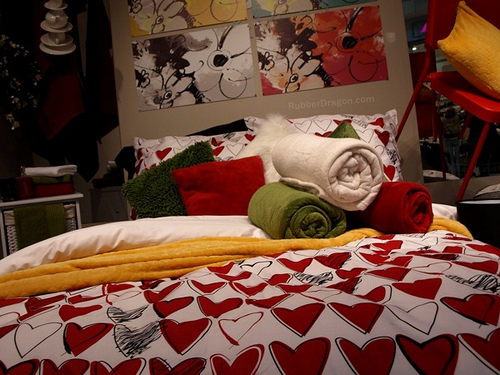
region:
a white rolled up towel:
[302, 131, 387, 209]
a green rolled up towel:
[265, 199, 340, 240]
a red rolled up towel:
[385, 174, 436, 230]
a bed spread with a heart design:
[113, 238, 470, 365]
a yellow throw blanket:
[0, 231, 284, 315]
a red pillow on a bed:
[208, 147, 263, 208]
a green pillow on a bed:
[137, 153, 187, 221]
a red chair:
[380, 15, 450, 202]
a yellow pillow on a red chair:
[438, 11, 485, 83]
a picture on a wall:
[124, 14, 256, 129]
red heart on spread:
[266, 304, 329, 331]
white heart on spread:
[215, 314, 266, 342]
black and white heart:
[113, 319, 163, 356]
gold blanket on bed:
[118, 251, 162, 272]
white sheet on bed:
[144, 224, 181, 236]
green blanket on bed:
[273, 194, 291, 212]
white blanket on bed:
[306, 144, 328, 166]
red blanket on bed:
[390, 194, 404, 214]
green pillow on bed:
[143, 174, 158, 195]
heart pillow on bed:
[220, 140, 232, 152]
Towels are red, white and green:
[239, 128, 434, 246]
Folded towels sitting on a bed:
[120, 109, 475, 372]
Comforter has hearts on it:
[4, 227, 499, 371]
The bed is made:
[1, 115, 498, 374]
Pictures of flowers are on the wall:
[120, 0, 405, 118]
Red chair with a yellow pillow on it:
[383, 0, 495, 210]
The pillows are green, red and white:
[113, 113, 310, 235]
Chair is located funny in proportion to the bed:
[21, 0, 494, 374]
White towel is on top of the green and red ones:
[239, 121, 442, 248]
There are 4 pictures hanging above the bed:
[106, 1, 416, 315]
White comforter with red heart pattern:
[0, 228, 499, 373]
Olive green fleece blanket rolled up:
[245, 182, 348, 241]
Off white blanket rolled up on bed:
[273, 131, 382, 210]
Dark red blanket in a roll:
[365, 182, 434, 235]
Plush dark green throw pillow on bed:
[123, 142, 218, 219]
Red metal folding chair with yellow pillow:
[390, 0, 499, 208]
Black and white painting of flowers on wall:
[128, 23, 258, 108]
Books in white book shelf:
[0, 193, 87, 256]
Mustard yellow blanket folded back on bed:
[1, 215, 468, 297]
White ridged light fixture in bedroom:
[36, 1, 74, 56]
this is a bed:
[2, 114, 498, 374]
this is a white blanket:
[272, 134, 387, 209]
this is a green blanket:
[245, 180, 350, 241]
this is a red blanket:
[348, 174, 435, 238]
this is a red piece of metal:
[383, 0, 498, 225]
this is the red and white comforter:
[0, 214, 489, 369]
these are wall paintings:
[127, 3, 390, 120]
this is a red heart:
[270, 298, 325, 338]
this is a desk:
[0, 188, 88, 255]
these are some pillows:
[119, 106, 406, 221]